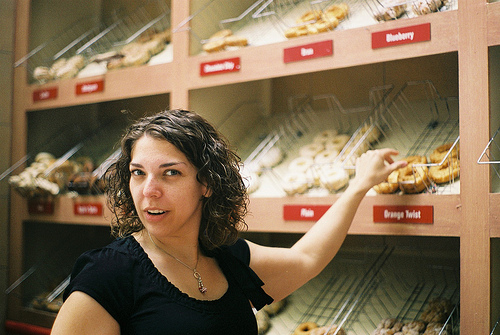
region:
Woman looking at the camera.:
[106, 102, 246, 253]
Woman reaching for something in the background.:
[40, 100, 400, 331]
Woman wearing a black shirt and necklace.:
[62, 107, 272, 332]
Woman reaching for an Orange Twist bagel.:
[40, 100, 466, 331]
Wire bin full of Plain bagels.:
[250, 90, 370, 196]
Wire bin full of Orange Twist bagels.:
[350, 76, 480, 197]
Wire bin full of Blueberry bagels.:
[355, 0, 455, 46]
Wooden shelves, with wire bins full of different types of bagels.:
[11, 0, 496, 330]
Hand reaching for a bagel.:
[340, 71, 467, 200]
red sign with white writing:
[368, 25, 432, 52]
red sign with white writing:
[281, 43, 333, 58]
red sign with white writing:
[196, 57, 242, 74]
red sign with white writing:
[74, 80, 102, 95]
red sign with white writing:
[30, 88, 59, 103]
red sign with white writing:
[26, 196, 54, 215]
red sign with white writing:
[71, 201, 101, 218]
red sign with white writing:
[281, 205, 327, 222]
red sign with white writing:
[369, 203, 433, 225]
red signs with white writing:
[193, 20, 430, 76]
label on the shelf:
[366, 23, 437, 50]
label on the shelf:
[273, 34, 335, 68]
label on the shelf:
[188, 52, 240, 79]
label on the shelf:
[73, 78, 105, 102]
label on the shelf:
[31, 86, 59, 106]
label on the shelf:
[73, 201, 103, 219]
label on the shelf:
[374, 203, 436, 228]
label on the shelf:
[283, 200, 335, 225]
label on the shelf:
[66, 198, 101, 220]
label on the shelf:
[15, 203, 60, 217]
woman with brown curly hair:
[106, 110, 247, 256]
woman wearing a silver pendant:
[148, 230, 209, 294]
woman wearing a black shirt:
[65, 218, 259, 333]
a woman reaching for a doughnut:
[51, 110, 414, 332]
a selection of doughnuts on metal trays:
[13, 4, 459, 195]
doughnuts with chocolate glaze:
[66, 171, 116, 196]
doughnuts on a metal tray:
[374, 294, 454, 334]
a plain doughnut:
[295, 319, 320, 334]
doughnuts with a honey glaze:
[287, 5, 347, 37]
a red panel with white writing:
[370, 24, 435, 46]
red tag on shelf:
[61, 190, 111, 222]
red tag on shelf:
[278, 190, 335, 227]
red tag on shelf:
[363, 198, 438, 235]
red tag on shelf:
[23, 81, 64, 103]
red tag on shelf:
[73, 74, 113, 99]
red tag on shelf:
[185, 53, 249, 79]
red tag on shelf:
[273, 33, 350, 70]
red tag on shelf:
[362, 18, 434, 51]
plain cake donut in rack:
[390, 156, 427, 193]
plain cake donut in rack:
[430, 153, 462, 185]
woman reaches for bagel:
[48, 103, 408, 333]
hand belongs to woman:
[350, 143, 407, 184]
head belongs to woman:
[114, 108, 251, 243]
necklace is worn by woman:
[144, 228, 211, 297]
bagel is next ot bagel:
[434, 142, 457, 163]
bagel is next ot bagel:
[430, 158, 460, 183]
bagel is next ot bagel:
[398, 162, 428, 190]